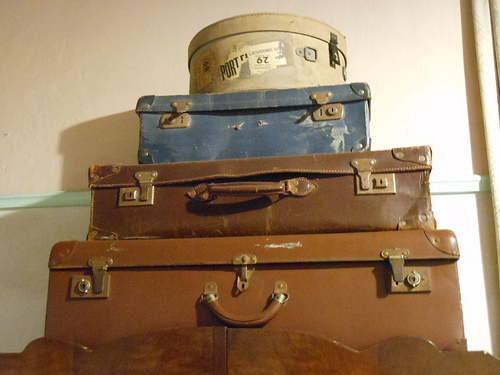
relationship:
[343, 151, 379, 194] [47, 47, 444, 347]
latch on suitcase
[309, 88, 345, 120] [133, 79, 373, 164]
latch on suitcase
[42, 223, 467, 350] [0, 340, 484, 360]
box on floor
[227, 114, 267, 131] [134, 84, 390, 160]
holes in suitcase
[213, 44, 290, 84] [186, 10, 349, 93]
sticker on box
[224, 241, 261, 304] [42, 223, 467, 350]
latch on box